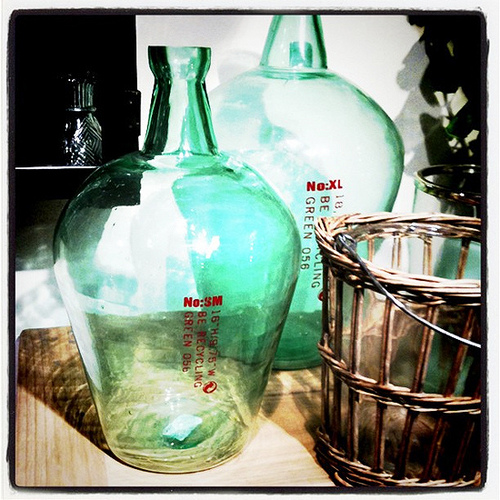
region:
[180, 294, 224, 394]
the red print on the glass jar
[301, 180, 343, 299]
the red print on the glass jar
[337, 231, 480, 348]
the metal handle on the basket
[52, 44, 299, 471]
the glass jar with a blue tint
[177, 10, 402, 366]
the glass jar with a blue tint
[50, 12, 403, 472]
the glass jars with a blue tint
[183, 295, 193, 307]
the red letter "N"on the glass jar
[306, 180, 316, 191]
the red letter "N"on the glass jar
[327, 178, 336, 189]
the red letter "X"on the glass jar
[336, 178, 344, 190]
the red letter "L"on the glass jar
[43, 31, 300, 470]
Green glass bottle sized small a green glass bottle labled small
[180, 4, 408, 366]
a green glass bottle labled Extra large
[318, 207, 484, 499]
a woven basket with a metal handle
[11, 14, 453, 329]
a white wall behind bottles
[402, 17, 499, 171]
a tall house plant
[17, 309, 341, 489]
a natural wood table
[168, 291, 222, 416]
red print on green bottles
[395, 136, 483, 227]
a silver trimmed glass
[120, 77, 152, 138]
a black hinge on a cabinet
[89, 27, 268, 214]
the narrow neck for a wide bottle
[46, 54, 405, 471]
two glass jars on table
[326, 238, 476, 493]
basket next to glass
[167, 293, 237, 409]
writing on the glass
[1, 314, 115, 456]
shadow of the glass on table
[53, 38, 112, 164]
vase on the shelf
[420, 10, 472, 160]
green leaves on the side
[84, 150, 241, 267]
reflection on the glass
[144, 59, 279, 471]
jar is green colored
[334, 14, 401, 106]
wall is white in back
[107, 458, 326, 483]
white object under glass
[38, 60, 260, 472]
vase on the table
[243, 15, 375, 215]
vase on the table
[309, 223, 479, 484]
basket on the table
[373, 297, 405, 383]
straw on the basket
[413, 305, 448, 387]
straw on the basket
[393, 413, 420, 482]
straw on the basket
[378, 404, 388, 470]
straw on the basket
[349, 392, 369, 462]
straw on the basket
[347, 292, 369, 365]
straw on the basket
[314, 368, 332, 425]
straw on the basket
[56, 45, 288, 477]
green tinted bottle on the table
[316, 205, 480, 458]
wicker basket on the table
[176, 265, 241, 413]
red writing on the bottle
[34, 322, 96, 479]
wooden table next to the wall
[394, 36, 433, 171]
shadows on the wall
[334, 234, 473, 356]
wire handle on the basket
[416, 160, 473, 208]
metal rimmed glass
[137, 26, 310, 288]
two green bottles together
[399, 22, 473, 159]
plant on the table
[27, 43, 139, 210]
brown shelf above the table